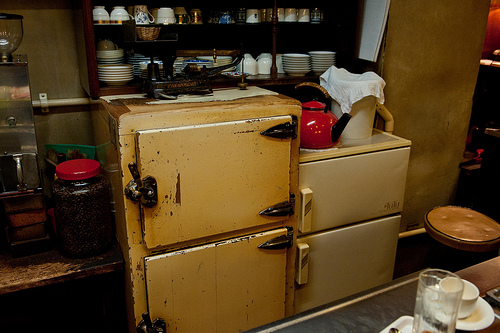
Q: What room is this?
A: Kitchen.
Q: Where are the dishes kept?
A: On the shelf.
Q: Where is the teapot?
A: On the refrigerator.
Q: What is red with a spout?
A: A tea kettle.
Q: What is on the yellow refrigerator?
A: Rust.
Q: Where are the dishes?
A: Shelf.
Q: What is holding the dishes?
A: Shelf.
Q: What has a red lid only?
A: Jar.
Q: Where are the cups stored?
A: Shelf.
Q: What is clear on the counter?
A: Glass.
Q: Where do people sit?
A: The chair.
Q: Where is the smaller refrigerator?
A: Next to the big refrigerator.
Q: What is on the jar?
A: A red lid.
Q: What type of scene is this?
A: Indoor.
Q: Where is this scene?
A: Kitchen.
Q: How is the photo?
A: Clear.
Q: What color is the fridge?
A: White.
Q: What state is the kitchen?
A: Old.